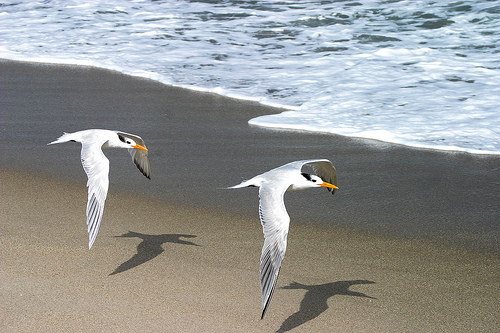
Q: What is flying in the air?
A: Seagulls.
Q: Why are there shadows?
A: Sunny day.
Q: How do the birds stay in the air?
A: Flapping wings.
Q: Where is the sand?
A: Below birds.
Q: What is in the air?
A: Birds.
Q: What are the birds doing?
A: Flying.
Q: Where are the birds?
A: At the beach.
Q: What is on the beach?
A: Sand.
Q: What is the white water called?
A: Foam.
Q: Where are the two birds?
A: In the air.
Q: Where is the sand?
A: On the beach.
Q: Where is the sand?
A: On the shore.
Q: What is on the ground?
A: Shadows.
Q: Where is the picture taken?
A: A beach.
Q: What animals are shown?
A: Seagulls.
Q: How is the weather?
A: Sunny.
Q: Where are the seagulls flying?
A: Over the beach.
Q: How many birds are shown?
A: Two.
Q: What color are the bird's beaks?
A: Orange.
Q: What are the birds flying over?
A: Sand.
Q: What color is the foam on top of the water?
A: White.